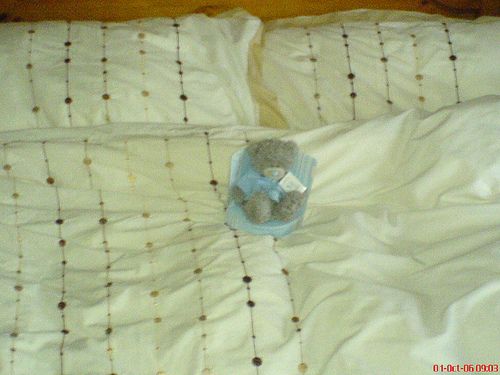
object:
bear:
[233, 136, 307, 225]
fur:
[264, 144, 283, 162]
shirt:
[237, 170, 287, 203]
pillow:
[0, 7, 265, 144]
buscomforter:
[5, 3, 498, 373]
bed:
[0, 0, 500, 375]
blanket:
[0, 96, 500, 375]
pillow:
[261, 8, 499, 132]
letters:
[433, 364, 500, 375]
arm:
[236, 172, 253, 195]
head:
[245, 139, 299, 179]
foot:
[273, 191, 306, 221]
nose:
[272, 172, 279, 176]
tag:
[278, 172, 307, 195]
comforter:
[1, 8, 498, 373]